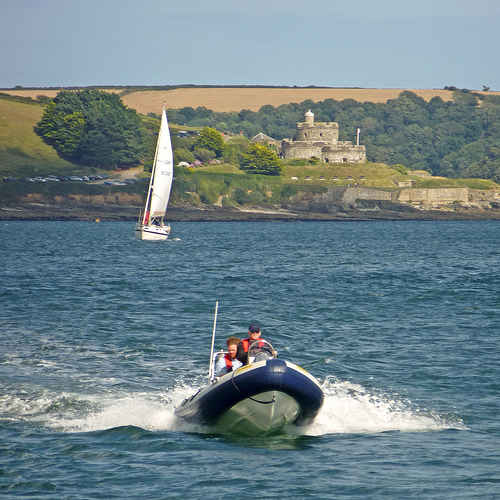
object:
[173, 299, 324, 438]
boat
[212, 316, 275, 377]
people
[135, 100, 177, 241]
sailboat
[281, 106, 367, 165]
building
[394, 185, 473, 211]
wall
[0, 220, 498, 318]
water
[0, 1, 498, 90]
sky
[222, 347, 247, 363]
vests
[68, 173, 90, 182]
cars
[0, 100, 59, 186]
hills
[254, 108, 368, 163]
castle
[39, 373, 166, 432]
waves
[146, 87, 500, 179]
trees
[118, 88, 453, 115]
farmland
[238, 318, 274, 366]
driver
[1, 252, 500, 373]
waters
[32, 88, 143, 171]
bush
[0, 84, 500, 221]
background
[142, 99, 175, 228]
sail